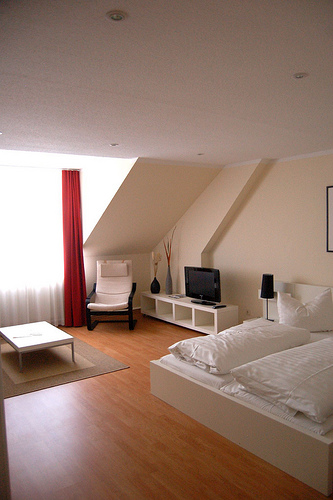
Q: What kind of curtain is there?
A: Red.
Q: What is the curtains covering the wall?
A: White sheer.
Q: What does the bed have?
A: White linen.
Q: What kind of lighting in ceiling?
A: Recessed lighting.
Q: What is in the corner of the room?
A: A chair.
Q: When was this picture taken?
A: During the day.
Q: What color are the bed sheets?
A: White.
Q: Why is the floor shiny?
A: Because it is hardwood.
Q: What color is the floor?
A: Brown.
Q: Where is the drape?
A: Over the window.